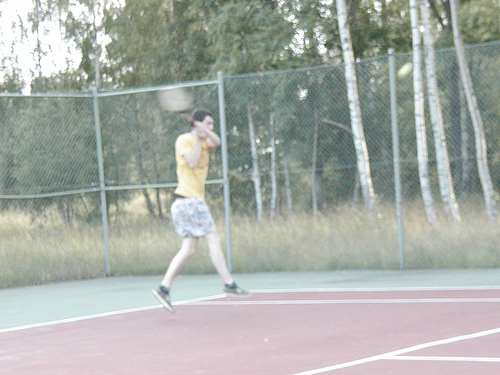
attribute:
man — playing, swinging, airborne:
[151, 104, 251, 313]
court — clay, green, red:
[1, 265, 498, 372]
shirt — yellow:
[176, 131, 211, 199]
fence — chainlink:
[0, 39, 499, 290]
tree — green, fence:
[28, 3, 323, 97]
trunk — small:
[245, 103, 263, 218]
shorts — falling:
[167, 199, 215, 235]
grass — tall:
[0, 195, 500, 290]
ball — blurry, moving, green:
[397, 60, 414, 79]